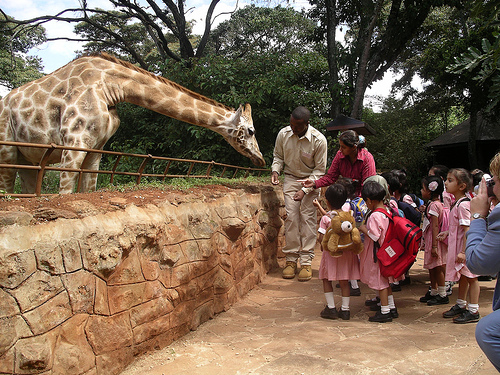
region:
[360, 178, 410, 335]
This is a child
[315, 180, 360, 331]
This is a child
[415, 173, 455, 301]
This is a child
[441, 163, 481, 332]
This is a child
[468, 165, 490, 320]
This is a child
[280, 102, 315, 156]
Head of a person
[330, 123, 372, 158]
Head of a person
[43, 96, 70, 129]
Small brown spot on a giraffe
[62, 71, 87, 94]
Small brown spot on a giraffe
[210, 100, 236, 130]
Small brown spot on a giraffe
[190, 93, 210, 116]
Small brown spot on a giraffe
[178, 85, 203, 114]
Small brown spot on a giraffe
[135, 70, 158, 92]
Small brown spot on a giraffe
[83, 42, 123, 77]
Small brown spot on a giraffe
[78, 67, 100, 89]
Small brown spot on a giraffe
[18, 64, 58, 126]
Small brown spot on a giraffe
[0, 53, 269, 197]
a brown and tan giraffe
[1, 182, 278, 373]
a brown rock wall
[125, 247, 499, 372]
a brown rock path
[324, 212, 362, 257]
a brown plush teddy bear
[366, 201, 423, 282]
a large red back pack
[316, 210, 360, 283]
a little girl's pink dress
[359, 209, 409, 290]
a little girl's pink dress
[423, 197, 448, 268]
a little girl's pink dress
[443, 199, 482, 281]
a little girl's pink dress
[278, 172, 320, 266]
a pair of tan pants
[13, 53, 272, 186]
There is a giraffee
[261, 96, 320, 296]
There is a male tour guide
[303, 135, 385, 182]
There is a female in a red shirt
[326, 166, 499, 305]
There is a group of little girls in pink dresses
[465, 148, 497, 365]
There is a man taking a photo of the giraffe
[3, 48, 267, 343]
The giraffe is behind a fence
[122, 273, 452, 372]
The ground is made of cement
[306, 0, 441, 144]
there are tall trees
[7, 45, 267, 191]
The giraffe is brown and white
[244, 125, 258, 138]
The giraffes eye is black.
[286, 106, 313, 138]
The man has black hair.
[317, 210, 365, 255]
The girl is wearing a teddy bear back pack.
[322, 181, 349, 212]
The girl has black hair.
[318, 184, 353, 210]
The girl has short hair.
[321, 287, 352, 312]
The girl is wearing white socks.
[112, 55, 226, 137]
The giraffe has a long neck.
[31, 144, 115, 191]
The fence is made of metal.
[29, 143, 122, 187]
The fence is brown.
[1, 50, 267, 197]
Giraffe reaching over fence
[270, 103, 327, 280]
Black man in khaki uniform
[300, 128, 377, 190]
Black haired woman in pink shirt